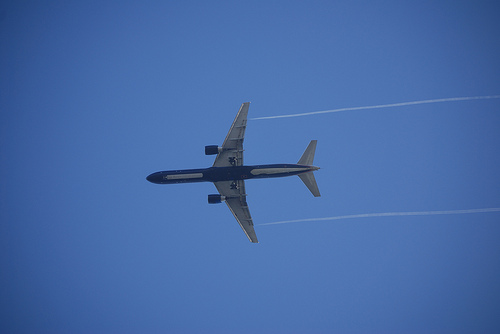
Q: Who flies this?
A: A pilot.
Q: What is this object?
A: A plane.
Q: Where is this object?
A: The sky.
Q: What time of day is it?
A: Daytime.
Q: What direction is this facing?
A: Left.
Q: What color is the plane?
A: Blue and gray.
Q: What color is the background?
A: Blue.